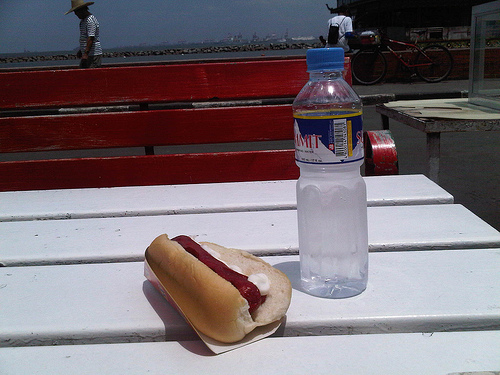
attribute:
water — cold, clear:
[296, 159, 368, 297]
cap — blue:
[305, 48, 345, 71]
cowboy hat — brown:
[64, 1, 95, 16]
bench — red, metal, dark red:
[1, 57, 398, 193]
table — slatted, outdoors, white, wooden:
[1, 173, 500, 373]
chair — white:
[376, 1, 499, 184]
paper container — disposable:
[143, 260, 282, 354]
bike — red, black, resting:
[349, 23, 455, 84]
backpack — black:
[326, 25, 341, 43]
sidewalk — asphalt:
[2, 97, 499, 231]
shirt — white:
[327, 14, 354, 51]